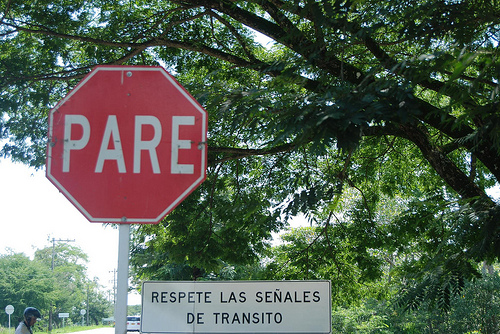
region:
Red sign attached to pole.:
[71, 76, 210, 233]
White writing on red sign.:
[63, 75, 168, 166]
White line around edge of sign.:
[91, 60, 177, 108]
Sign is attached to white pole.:
[92, 187, 152, 327]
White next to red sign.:
[133, 262, 364, 324]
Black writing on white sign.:
[140, 277, 315, 331]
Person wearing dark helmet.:
[18, 297, 59, 322]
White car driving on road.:
[122, 310, 141, 328]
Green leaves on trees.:
[401, 251, 436, 308]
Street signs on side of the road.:
[46, 297, 98, 325]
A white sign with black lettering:
[140, 282, 335, 332]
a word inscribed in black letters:
[150, 288, 217, 303]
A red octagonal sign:
[39, 62, 220, 222]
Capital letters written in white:
[57, 107, 202, 177]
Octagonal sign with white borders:
[42, 63, 217, 225]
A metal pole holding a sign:
[109, 226, 137, 327]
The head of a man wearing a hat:
[15, 297, 46, 332]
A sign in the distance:
[3, 293, 18, 332]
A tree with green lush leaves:
[255, 43, 497, 198]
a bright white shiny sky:
[3, 177, 46, 239]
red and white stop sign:
[40, 64, 215, 229]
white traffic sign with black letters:
[140, 273, 340, 333]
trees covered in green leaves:
[215, 5, 498, 160]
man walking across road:
[13, 303, 41, 333]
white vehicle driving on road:
[119, 311, 143, 332]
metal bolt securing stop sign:
[121, 69, 135, 81]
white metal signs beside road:
[55, 306, 90, 328]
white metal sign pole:
[111, 223, 128, 333]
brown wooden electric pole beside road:
[39, 226, 83, 259]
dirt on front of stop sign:
[184, 128, 210, 153]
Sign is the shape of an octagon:
[41, 59, 211, 226]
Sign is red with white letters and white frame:
[43, 63, 209, 225]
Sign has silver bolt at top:
[118, 70, 137, 80]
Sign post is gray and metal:
[114, 222, 139, 332]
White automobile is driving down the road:
[125, 311, 145, 331]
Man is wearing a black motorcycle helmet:
[21, 303, 46, 331]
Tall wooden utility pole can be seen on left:
[45, 226, 70, 330]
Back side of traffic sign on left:
[0, 297, 19, 331]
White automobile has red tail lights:
[126, 320, 141, 328]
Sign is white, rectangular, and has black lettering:
[136, 274, 338, 332]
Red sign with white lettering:
[29, 51, 236, 238]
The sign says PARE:
[32, 100, 204, 182]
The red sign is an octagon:
[35, 57, 259, 241]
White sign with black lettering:
[113, 270, 345, 331]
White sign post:
[104, 218, 141, 328]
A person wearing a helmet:
[10, 297, 45, 327]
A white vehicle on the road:
[121, 316, 143, 330]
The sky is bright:
[11, 154, 173, 319]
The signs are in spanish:
[32, 42, 343, 327]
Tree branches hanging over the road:
[15, 10, 493, 237]